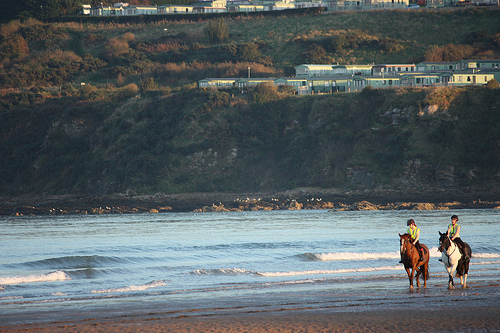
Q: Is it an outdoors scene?
A: Yes, it is outdoors.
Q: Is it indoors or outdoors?
A: It is outdoors.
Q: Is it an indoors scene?
A: No, it is outdoors.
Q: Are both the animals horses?
A: Yes, all the animals are horses.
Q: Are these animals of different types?
A: No, all the animals are horses.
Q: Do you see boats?
A: No, there are no boats.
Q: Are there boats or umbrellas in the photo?
A: No, there are no boats or umbrellas.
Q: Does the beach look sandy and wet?
A: Yes, the beach is sandy and wet.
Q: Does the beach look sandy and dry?
A: No, the beach is sandy but wet.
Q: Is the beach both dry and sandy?
A: No, the beach is sandy but wet.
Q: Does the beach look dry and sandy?
A: No, the beach is sandy but wet.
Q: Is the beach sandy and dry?
A: No, the beach is sandy but wet.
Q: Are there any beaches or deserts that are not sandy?
A: No, there is a beach but it is sandy.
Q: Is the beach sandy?
A: Yes, the beach is sandy.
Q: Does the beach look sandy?
A: Yes, the beach is sandy.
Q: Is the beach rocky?
A: No, the beach is sandy.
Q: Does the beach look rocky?
A: No, the beach is sandy.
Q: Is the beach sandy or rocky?
A: The beach is sandy.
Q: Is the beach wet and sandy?
A: Yes, the beach is wet and sandy.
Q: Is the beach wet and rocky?
A: No, the beach is wet but sandy.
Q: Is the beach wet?
A: Yes, the beach is wet.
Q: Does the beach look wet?
A: Yes, the beach is wet.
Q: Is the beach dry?
A: No, the beach is wet.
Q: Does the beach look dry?
A: No, the beach is wet.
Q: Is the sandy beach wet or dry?
A: The beach is wet.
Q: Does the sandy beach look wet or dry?
A: The beach is wet.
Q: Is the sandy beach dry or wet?
A: The beach is wet.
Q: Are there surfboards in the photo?
A: No, there are no surfboards.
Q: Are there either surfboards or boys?
A: No, there are no surfboards or boys.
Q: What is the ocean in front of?
A: The ocean is in front of the hill.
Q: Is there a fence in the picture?
A: No, there are no fences.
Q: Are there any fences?
A: No, there are no fences.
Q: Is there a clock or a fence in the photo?
A: No, there are no fences or clocks.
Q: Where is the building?
A: The building is on the hill.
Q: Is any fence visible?
A: No, there are no fences.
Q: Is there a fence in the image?
A: No, there are no fences.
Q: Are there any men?
A: No, there are no men.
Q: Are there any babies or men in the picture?
A: No, there are no men or babies.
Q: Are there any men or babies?
A: No, there are no men or babies.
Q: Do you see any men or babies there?
A: No, there are no men or babies.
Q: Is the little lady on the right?
A: Yes, the lady is on the right of the image.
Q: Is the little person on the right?
A: Yes, the lady is on the right of the image.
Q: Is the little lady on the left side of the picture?
A: No, the lady is on the right of the image.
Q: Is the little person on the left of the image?
A: No, the lady is on the right of the image.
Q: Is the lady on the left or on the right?
A: The lady is on the right of the image.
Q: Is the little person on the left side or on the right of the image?
A: The lady is on the right of the image.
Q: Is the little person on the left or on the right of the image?
A: The lady is on the right of the image.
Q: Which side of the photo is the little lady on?
A: The lady is on the right of the image.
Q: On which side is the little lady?
A: The lady is on the right of the image.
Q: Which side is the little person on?
A: The lady is on the right of the image.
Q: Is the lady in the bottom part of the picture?
A: Yes, the lady is in the bottom of the image.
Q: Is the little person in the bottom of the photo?
A: Yes, the lady is in the bottom of the image.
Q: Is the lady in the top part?
A: No, the lady is in the bottom of the image.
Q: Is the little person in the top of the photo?
A: No, the lady is in the bottom of the image.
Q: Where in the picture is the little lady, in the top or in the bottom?
A: The lady is in the bottom of the image.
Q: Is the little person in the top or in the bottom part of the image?
A: The lady is in the bottom of the image.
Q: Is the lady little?
A: Yes, the lady is little.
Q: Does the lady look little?
A: Yes, the lady is little.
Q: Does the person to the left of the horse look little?
A: Yes, the lady is little.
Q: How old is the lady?
A: The lady is little.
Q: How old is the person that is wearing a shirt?
A: The lady is little.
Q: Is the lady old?
A: No, the lady is little.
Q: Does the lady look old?
A: No, the lady is little.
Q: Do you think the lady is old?
A: No, the lady is little.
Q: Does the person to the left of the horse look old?
A: No, the lady is little.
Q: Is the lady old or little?
A: The lady is little.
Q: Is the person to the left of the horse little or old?
A: The lady is little.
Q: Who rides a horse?
A: The lady rides a horse.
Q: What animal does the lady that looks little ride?
A: The lady rides a horse.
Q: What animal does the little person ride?
A: The lady rides a horse.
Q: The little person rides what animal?
A: The lady rides a horse.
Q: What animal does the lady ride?
A: The lady rides a horse.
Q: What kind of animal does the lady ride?
A: The lady rides a horse.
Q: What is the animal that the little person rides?
A: The animal is a horse.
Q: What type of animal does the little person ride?
A: The lady rides a horse.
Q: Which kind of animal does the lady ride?
A: The lady rides a horse.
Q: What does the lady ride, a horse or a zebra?
A: The lady rides a horse.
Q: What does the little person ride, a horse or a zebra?
A: The lady rides a horse.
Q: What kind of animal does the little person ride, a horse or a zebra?
A: The lady rides a horse.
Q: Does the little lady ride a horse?
A: Yes, the lady rides a horse.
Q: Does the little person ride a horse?
A: Yes, the lady rides a horse.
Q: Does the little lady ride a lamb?
A: No, the lady rides a horse.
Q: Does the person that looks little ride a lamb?
A: No, the lady rides a horse.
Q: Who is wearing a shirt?
A: The lady is wearing a shirt.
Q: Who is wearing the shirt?
A: The lady is wearing a shirt.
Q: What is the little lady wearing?
A: The lady is wearing a shirt.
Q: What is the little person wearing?
A: The lady is wearing a shirt.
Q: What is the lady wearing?
A: The lady is wearing a shirt.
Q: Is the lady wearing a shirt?
A: Yes, the lady is wearing a shirt.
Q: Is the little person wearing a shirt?
A: Yes, the lady is wearing a shirt.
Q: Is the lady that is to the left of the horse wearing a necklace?
A: No, the lady is wearing a shirt.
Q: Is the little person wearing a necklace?
A: No, the lady is wearing a shirt.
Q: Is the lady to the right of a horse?
A: No, the lady is to the left of a horse.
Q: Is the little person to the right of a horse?
A: No, the lady is to the left of a horse.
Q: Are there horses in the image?
A: Yes, there is a horse.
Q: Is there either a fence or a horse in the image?
A: Yes, there is a horse.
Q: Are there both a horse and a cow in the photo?
A: No, there is a horse but no cows.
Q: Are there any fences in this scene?
A: No, there are no fences.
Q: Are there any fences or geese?
A: No, there are no fences or geese.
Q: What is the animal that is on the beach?
A: The animal is a horse.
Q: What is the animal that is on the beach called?
A: The animal is a horse.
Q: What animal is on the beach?
A: The animal is a horse.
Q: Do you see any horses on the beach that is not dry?
A: Yes, there is a horse on the beach.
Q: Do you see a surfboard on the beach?
A: No, there is a horse on the beach.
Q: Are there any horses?
A: Yes, there is a horse.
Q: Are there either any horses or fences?
A: Yes, there is a horse.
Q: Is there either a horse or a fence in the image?
A: Yes, there is a horse.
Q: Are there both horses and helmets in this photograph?
A: Yes, there are both a horse and a helmet.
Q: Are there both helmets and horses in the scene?
A: Yes, there are both a horse and a helmet.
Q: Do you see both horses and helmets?
A: Yes, there are both a horse and a helmet.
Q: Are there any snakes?
A: No, there are no snakes.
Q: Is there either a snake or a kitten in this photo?
A: No, there are no snakes or kittens.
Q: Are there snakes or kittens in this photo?
A: No, there are no snakes or kittens.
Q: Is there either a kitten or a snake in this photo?
A: No, there are no snakes or kittens.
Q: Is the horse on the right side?
A: Yes, the horse is on the right of the image.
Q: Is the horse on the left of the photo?
A: No, the horse is on the right of the image.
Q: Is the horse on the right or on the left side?
A: The horse is on the right of the image.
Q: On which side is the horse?
A: The horse is on the right of the image.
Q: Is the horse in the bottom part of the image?
A: Yes, the horse is in the bottom of the image.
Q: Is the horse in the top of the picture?
A: No, the horse is in the bottom of the image.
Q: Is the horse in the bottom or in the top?
A: The horse is in the bottom of the image.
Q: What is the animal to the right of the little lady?
A: The animal is a horse.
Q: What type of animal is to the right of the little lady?
A: The animal is a horse.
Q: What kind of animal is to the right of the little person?
A: The animal is a horse.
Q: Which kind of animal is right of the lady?
A: The animal is a horse.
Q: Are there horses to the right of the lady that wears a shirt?
A: Yes, there is a horse to the right of the lady.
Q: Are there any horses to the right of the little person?
A: Yes, there is a horse to the right of the lady.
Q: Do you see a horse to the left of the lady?
A: No, the horse is to the right of the lady.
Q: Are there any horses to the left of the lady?
A: No, the horse is to the right of the lady.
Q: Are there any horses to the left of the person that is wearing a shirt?
A: No, the horse is to the right of the lady.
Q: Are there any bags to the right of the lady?
A: No, there is a horse to the right of the lady.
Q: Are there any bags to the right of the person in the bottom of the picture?
A: No, there is a horse to the right of the lady.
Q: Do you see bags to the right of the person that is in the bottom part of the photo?
A: No, there is a horse to the right of the lady.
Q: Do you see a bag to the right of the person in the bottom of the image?
A: No, there is a horse to the right of the lady.